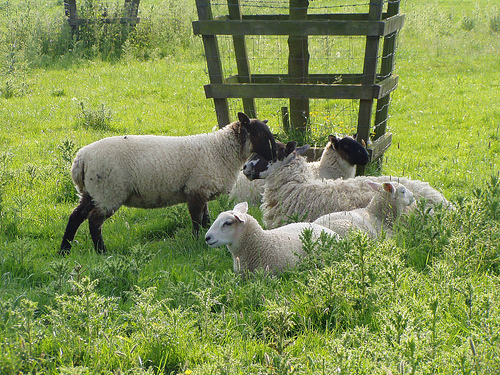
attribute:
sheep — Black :
[206, 205, 333, 273]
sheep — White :
[205, 174, 427, 289]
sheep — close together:
[74, 90, 461, 316]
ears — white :
[364, 175, 396, 195]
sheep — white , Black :
[200, 206, 320, 268]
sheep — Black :
[64, 111, 276, 243]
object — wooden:
[187, 0, 407, 179]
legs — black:
[55, 194, 110, 259]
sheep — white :
[316, 182, 417, 279]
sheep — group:
[41, 112, 474, 290]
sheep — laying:
[198, 196, 351, 292]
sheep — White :
[210, 210, 340, 283]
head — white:
[203, 210, 249, 247]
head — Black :
[228, 105, 277, 162]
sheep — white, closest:
[205, 197, 342, 275]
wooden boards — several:
[184, 26, 463, 148]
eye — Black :
[221, 217, 234, 227]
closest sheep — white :
[201, 200, 341, 277]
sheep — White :
[205, 199, 348, 280]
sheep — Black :
[52, 94, 279, 249]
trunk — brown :
[283, 4, 313, 134]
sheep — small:
[314, 178, 417, 238]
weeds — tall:
[1, 3, 484, 371]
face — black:
[239, 111, 278, 156]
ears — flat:
[231, 198, 251, 226]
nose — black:
[265, 151, 275, 161]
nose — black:
[360, 150, 370, 164]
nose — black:
[240, 162, 248, 168]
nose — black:
[410, 193, 416, 201]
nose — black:
[201, 234, 212, 244]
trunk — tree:
[287, 7, 313, 146]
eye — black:
[340, 139, 349, 148]